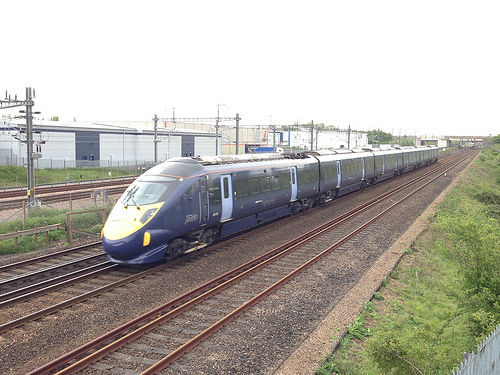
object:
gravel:
[1, 129, 481, 372]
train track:
[75, 146, 480, 373]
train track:
[0, 239, 139, 330]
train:
[100, 144, 439, 265]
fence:
[448, 324, 500, 375]